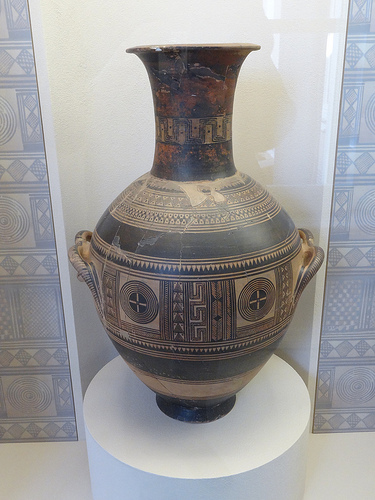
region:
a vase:
[65, 43, 347, 431]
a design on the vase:
[152, 284, 242, 348]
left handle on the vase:
[298, 220, 323, 285]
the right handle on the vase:
[67, 232, 90, 264]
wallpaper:
[337, 201, 372, 267]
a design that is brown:
[117, 283, 157, 320]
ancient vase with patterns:
[65, 42, 326, 427]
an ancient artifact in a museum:
[63, 42, 328, 426]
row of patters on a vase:
[91, 230, 302, 365]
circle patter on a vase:
[117, 272, 159, 329]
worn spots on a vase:
[163, 168, 252, 213]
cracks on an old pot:
[102, 216, 189, 276]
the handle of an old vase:
[285, 217, 326, 312]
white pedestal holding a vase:
[79, 345, 317, 498]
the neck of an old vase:
[115, 37, 265, 175]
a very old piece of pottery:
[62, 40, 330, 428]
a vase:
[70, 35, 340, 423]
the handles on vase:
[67, 222, 326, 297]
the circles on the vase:
[117, 276, 277, 329]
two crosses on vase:
[126, 289, 267, 315]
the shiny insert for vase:
[27, 0, 351, 442]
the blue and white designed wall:
[1, 1, 371, 436]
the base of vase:
[155, 390, 233, 420]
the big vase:
[66, 38, 323, 422]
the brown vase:
[68, 38, 326, 425]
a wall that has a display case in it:
[1, 0, 373, 497]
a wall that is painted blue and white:
[3, 4, 373, 497]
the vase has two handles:
[25, 29, 340, 431]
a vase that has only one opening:
[32, 23, 350, 444]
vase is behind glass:
[32, 34, 347, 425]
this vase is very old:
[33, 26, 342, 438]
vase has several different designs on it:
[39, 48, 343, 424]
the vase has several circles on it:
[28, 33, 326, 424]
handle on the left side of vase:
[65, 227, 105, 311]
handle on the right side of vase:
[295, 224, 330, 297]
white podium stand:
[74, 347, 313, 499]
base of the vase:
[147, 394, 240, 426]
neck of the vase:
[148, 84, 241, 183]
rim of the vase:
[119, 42, 265, 54]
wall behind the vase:
[0, 0, 371, 484]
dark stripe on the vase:
[95, 209, 300, 262]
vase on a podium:
[57, 39, 332, 429]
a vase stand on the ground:
[80, 342, 311, 499]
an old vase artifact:
[67, 38, 330, 425]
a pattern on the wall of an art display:
[0, 0, 101, 453]